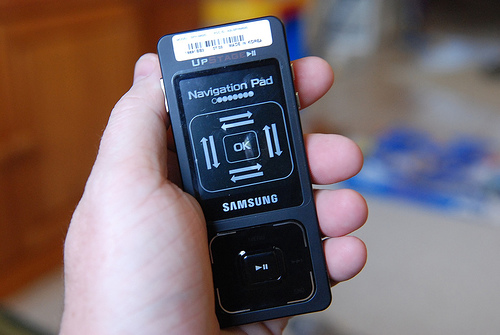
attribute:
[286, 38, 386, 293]
finger — four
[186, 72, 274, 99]
lettering — white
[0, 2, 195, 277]
wall — blurry, brown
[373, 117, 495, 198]
mat — blue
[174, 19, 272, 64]
sticker — white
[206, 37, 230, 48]
barcode — black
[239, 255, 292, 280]
button — play, pause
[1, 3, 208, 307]
cabinet — wood, brown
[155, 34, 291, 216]
cell phone — black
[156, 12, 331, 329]
cell phone — black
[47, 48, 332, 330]
hand — white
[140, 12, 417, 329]
phone — samsung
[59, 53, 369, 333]
hand — white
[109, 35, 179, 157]
thumb — resting